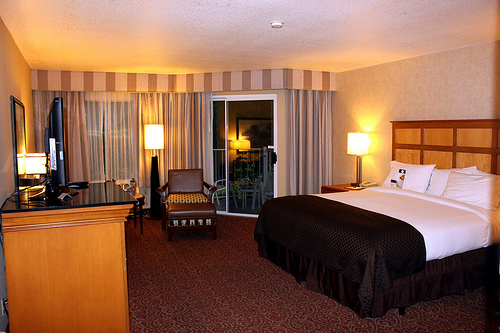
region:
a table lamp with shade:
[346, 132, 368, 187]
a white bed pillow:
[401, 164, 434, 192]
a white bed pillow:
[426, 167, 448, 194]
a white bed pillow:
[441, 169, 498, 209]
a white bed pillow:
[381, 159, 406, 188]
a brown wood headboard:
[388, 119, 498, 175]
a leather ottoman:
[164, 199, 219, 242]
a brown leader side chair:
[158, 167, 215, 204]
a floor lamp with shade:
[144, 124, 163, 219]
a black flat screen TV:
[45, 94, 69, 196]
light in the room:
[131, 108, 173, 228]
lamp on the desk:
[331, 111, 376, 184]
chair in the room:
[151, 159, 219, 214]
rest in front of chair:
[158, 196, 223, 238]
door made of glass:
[210, 98, 280, 207]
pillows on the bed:
[388, 163, 495, 208]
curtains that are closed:
[85, 98, 136, 185]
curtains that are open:
[154, 93, 332, 219]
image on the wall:
[6, 86, 34, 181]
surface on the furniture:
[18, 184, 130, 204]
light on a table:
[345, 120, 375, 165]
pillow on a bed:
[376, 151, 456, 196]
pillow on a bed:
[436, 167, 491, 207]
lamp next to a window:
[128, 117, 178, 162]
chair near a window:
[155, 165, 223, 238]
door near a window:
[222, 95, 272, 197]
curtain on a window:
[290, 100, 330, 172]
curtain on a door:
[175, 95, 206, 163]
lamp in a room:
[20, 141, 47, 174]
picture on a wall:
[10, 85, 35, 145]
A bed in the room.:
[256, 144, 493, 292]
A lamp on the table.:
[336, 131, 381, 191]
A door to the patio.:
[218, 105, 275, 225]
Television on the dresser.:
[46, 97, 71, 194]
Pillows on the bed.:
[403, 159, 490, 196]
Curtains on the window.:
[66, 100, 154, 206]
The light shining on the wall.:
[353, 98, 378, 131]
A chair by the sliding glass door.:
[160, 156, 218, 227]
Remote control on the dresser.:
[68, 174, 95, 187]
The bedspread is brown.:
[268, 182, 409, 267]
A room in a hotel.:
[1, 0, 499, 332]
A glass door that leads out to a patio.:
[207, 97, 275, 216]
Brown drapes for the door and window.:
[35, 89, 331, 216]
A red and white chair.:
[157, 167, 218, 232]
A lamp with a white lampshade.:
[346, 132, 375, 188]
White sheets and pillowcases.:
[310, 160, 497, 260]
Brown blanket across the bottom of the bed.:
[255, 196, 427, 321]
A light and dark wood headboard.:
[390, 121, 499, 172]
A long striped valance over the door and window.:
[26, 66, 338, 93]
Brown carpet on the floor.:
[0, 215, 499, 331]